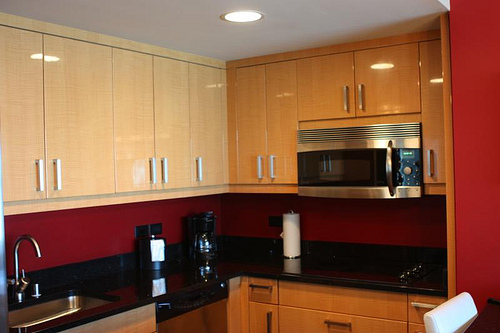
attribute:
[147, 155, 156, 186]
handle — silver, rectangular, long, metal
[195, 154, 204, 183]
handle — silver, long, rectangular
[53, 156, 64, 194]
handle — silver, long, rectangular, metal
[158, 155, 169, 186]
handle — silver, rectangular, long, metal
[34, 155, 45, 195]
handle — silver, long, rectangular, metal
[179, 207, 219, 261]
coffee maker — black, small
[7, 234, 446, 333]
counter — black, poly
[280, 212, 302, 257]
paper towels — white, rolled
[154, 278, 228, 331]
dishwasher — black, silver, chrome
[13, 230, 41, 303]
faucet — silver, tall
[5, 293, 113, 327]
sink — silver, stainless steel, basin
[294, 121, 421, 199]
microwave — silver, black, chrome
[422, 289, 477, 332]
chair — white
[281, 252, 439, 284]
stove — black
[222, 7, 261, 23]
recessed light — white, overhead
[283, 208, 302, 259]
towel holder — silver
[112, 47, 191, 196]
cabinet — wooden, wood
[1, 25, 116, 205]
cabinet — wooden, wood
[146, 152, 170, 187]
handles — metal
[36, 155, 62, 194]
handles — metal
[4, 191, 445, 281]
wall — dark red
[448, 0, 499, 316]
wall — dark red